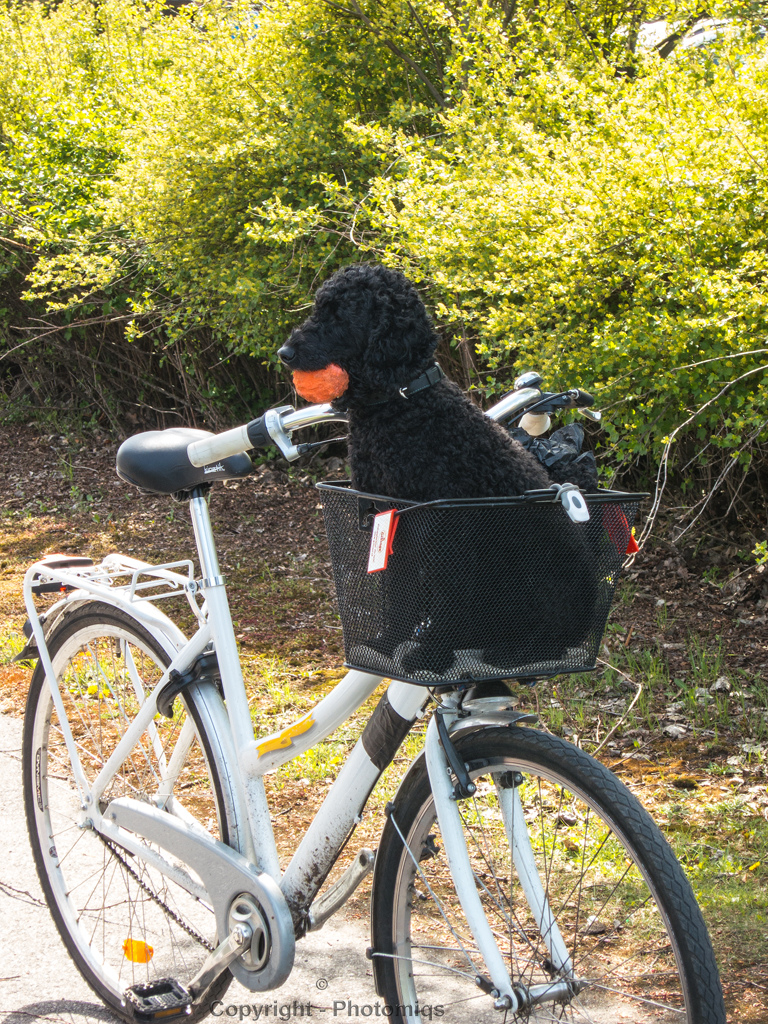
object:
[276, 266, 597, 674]
dog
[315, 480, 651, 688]
basket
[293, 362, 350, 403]
ball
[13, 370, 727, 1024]
bike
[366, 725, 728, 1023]
tire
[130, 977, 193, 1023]
pedal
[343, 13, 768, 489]
folliage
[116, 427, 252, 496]
seat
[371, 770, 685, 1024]
spokes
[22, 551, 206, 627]
storage rack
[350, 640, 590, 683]
blanket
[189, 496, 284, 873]
frame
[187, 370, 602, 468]
handlebar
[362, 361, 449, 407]
collar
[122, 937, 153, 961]
reflector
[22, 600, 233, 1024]
wheel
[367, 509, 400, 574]
tag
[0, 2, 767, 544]
background